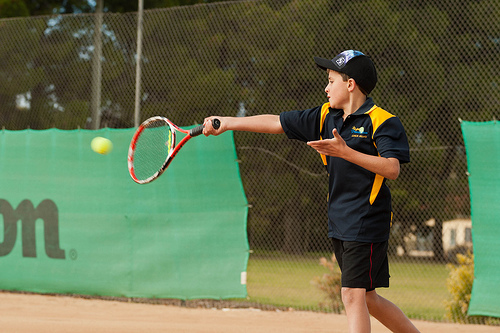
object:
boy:
[201, 50, 420, 333]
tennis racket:
[126, 115, 220, 185]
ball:
[88, 136, 115, 155]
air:
[0, 0, 226, 332]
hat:
[311, 49, 378, 94]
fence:
[0, 0, 498, 326]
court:
[0, 0, 499, 332]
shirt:
[278, 97, 411, 244]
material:
[458, 119, 500, 319]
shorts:
[328, 237, 390, 293]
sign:
[349, 125, 370, 139]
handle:
[191, 119, 222, 137]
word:
[349, 134, 366, 138]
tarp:
[0, 124, 252, 299]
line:
[367, 243, 373, 289]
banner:
[0, 122, 254, 300]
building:
[394, 194, 479, 257]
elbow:
[383, 166, 399, 180]